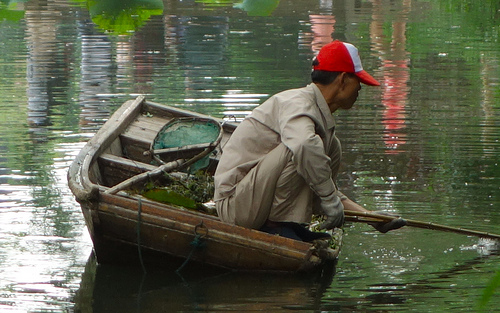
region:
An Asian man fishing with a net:
[221, 41, 380, 248]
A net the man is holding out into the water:
[325, 210, 499, 245]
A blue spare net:
[99, 113, 224, 214]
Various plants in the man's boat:
[140, 162, 213, 210]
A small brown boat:
[66, 94, 338, 272]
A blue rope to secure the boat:
[126, 204, 209, 275]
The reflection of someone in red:
[363, 3, 410, 154]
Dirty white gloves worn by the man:
[319, 192, 406, 232]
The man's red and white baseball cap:
[306, 40, 380, 85]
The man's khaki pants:
[213, 136, 340, 227]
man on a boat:
[200, 36, 429, 256]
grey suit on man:
[187, 21, 384, 272]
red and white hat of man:
[302, 39, 393, 86]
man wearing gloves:
[223, 25, 425, 297]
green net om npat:
[126, 96, 206, 170]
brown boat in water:
[81, 63, 339, 304]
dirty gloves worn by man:
[320, 191, 396, 244]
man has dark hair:
[295, 29, 390, 120]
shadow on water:
[332, 259, 492, 310]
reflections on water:
[63, 11, 483, 241]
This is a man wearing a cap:
[201, 38, 423, 253]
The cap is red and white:
[302, 39, 386, 106]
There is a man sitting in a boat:
[62, 23, 414, 305]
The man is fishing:
[227, 31, 495, 283]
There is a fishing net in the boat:
[143, 104, 236, 231]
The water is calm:
[5, 2, 483, 310]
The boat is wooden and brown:
[60, 86, 358, 303]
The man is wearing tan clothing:
[217, 81, 374, 273]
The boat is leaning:
[41, 70, 365, 306]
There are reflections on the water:
[10, 2, 499, 178]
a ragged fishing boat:
[105, 93, 339, 294]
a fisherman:
[188, 35, 433, 227]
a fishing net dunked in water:
[336, 191, 495, 257]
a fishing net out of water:
[79, 105, 243, 205]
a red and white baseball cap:
[298, 27, 431, 100]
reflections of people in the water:
[24, 18, 161, 85]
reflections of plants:
[13, 10, 167, 20]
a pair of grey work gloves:
[284, 209, 416, 234]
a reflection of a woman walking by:
[368, 10, 448, 185]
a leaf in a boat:
[134, 95, 156, 125]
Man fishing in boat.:
[59, 25, 499, 307]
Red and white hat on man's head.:
[303, 37, 383, 87]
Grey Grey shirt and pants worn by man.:
[208, 74, 313, 222]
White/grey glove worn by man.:
[319, 197, 352, 234]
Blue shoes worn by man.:
[262, 218, 337, 242]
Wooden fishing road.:
[346, 199, 498, 254]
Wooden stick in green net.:
[102, 111, 221, 203]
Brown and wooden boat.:
[51, 72, 220, 271]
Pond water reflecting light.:
[24, 33, 100, 118]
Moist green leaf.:
[70, 1, 172, 33]